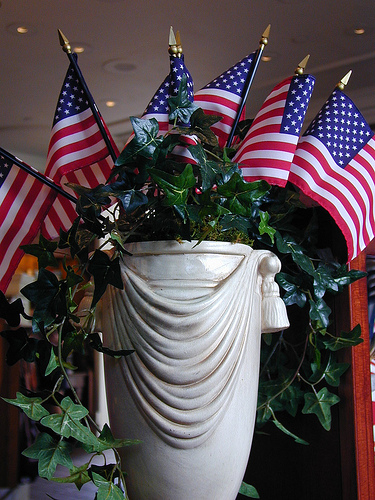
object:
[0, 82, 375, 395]
plant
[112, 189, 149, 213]
leaf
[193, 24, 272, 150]
flag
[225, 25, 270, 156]
pole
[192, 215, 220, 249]
twig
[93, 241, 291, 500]
vase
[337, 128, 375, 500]
door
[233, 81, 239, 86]
stars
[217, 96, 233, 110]
stripes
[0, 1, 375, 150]
ceiling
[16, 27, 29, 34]
lights